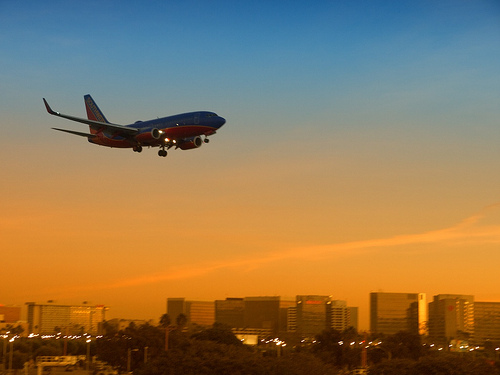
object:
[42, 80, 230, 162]
airplane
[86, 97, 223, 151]
plane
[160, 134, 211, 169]
wheel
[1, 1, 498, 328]
sky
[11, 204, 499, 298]
cloud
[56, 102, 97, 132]
wing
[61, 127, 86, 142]
wing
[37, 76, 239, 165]
airplane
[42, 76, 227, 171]
airplane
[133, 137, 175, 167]
wheels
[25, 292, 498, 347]
tall buildings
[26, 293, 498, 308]
flat tops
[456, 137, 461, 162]
ground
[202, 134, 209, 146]
front wheel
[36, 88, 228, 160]
plane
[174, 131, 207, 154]
engine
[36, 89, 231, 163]
airplane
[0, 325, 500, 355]
lights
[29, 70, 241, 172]
airplane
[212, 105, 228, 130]
nose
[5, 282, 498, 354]
cityscape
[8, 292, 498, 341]
buildings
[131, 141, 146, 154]
back wheel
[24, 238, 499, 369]
buildings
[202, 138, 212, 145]
wheel set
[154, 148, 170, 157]
wheel set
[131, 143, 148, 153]
wheel set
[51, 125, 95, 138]
side wing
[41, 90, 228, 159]
airplane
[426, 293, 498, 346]
building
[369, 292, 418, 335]
building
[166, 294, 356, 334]
building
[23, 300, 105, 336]
building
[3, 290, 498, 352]
cityscape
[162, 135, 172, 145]
light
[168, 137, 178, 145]
light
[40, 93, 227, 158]
plane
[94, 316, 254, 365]
trees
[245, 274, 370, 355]
building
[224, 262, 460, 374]
building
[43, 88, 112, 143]
tail fin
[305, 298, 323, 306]
sign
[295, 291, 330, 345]
building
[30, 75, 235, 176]
plane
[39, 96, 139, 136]
wing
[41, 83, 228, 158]
plane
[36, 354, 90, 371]
structure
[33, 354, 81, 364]
railing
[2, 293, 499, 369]
city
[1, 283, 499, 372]
city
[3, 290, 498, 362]
city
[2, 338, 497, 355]
roadway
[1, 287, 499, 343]
cityscape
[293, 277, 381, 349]
building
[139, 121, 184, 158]
engine